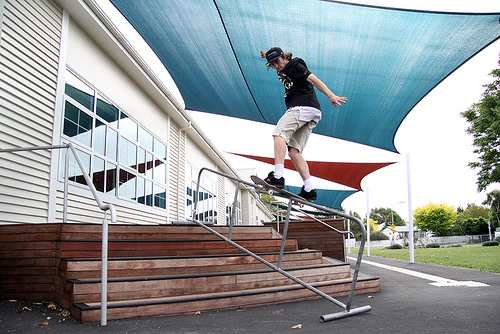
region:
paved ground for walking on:
[379, 280, 493, 326]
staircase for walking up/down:
[111, 215, 174, 307]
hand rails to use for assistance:
[60, 137, 118, 324]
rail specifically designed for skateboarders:
[188, 170, 359, 322]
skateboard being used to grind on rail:
[247, 173, 314, 205]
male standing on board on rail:
[259, 45, 319, 199]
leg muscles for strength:
[273, 133, 311, 190]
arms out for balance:
[258, 43, 343, 106]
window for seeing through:
[61, 69, 167, 211]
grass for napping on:
[443, 245, 483, 268]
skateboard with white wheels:
[252, 163, 319, 203]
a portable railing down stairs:
[189, 164, 369, 321]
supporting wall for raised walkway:
[281, 217, 366, 272]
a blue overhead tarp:
[91, 0, 494, 158]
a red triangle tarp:
[223, 147, 394, 194]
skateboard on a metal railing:
[248, 154, 327, 252]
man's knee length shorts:
[271, 107, 325, 158]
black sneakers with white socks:
[267, 167, 320, 206]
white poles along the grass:
[357, 155, 414, 261]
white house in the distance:
[385, 219, 422, 243]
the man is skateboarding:
[227, 43, 359, 196]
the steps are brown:
[151, 244, 221, 320]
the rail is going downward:
[153, 187, 385, 307]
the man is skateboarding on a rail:
[230, 12, 352, 325]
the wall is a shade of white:
[33, 25, 88, 76]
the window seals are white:
[72, 100, 178, 221]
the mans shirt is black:
[265, 49, 331, 140]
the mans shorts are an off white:
[215, 96, 333, 172]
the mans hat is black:
[252, 27, 294, 88]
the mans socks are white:
[248, 163, 297, 184]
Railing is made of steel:
[188, 168, 372, 319]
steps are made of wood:
[62, 222, 382, 323]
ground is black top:
[1, 264, 495, 332]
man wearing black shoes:
[246, 46, 343, 203]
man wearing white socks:
[246, 41, 351, 201]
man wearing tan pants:
[249, 40, 345, 205]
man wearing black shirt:
[250, 47, 345, 197]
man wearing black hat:
[250, 51, 338, 201]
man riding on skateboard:
[251, 47, 343, 210]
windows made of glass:
[59, 83, 168, 211]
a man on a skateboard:
[260, 45, 346, 200]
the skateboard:
[242, 176, 311, 206]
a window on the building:
[60, 68, 171, 210]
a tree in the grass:
[462, 53, 496, 210]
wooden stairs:
[64, 215, 375, 318]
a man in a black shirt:
[258, 50, 325, 199]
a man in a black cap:
[256, 46, 336, 197]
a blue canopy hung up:
[153, 0, 499, 154]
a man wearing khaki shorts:
[256, 45, 336, 201]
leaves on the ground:
[16, 296, 80, 328]